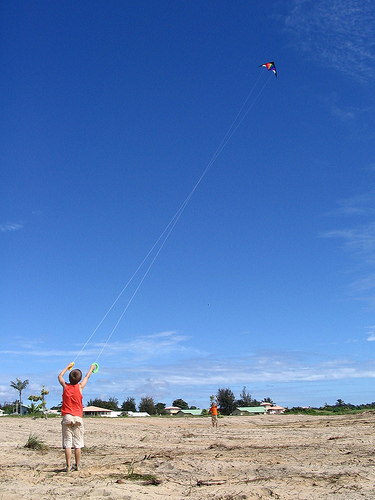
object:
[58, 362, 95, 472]
person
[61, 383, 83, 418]
shirt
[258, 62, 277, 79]
kite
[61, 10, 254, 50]
sky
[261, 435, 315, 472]
sand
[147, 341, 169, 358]
clouds